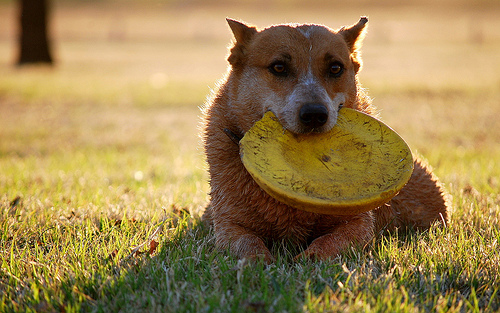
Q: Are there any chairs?
A: No, there are no chairs.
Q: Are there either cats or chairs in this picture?
A: No, there are no chairs or cats.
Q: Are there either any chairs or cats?
A: No, there are no chairs or cats.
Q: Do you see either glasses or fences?
A: No, there are no fences or glasses.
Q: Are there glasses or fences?
A: No, there are no fences or glasses.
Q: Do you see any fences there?
A: No, there are no fences.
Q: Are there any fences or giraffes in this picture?
A: No, there are no fences or giraffes.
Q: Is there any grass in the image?
A: Yes, there is grass.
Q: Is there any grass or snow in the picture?
A: Yes, there is grass.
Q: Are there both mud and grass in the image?
A: No, there is grass but no mud.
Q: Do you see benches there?
A: No, there are no benches.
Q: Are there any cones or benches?
A: No, there are no benches or cones.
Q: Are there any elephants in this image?
A: No, there are no elephants.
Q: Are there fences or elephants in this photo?
A: No, there are no elephants or fences.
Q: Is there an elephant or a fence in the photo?
A: No, there are no elephants or fences.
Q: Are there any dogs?
A: Yes, there is a dog.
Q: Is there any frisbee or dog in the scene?
A: Yes, there is a dog.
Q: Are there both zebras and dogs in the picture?
A: No, there is a dog but no zebras.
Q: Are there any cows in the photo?
A: No, there are no cows.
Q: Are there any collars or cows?
A: No, there are no cows or collars.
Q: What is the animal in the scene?
A: The animal is a dog.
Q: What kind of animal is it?
A: The animal is a dog.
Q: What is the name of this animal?
A: That is a dog.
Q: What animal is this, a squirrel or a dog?
A: That is a dog.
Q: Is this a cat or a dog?
A: This is a dog.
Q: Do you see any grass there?
A: Yes, there is grass.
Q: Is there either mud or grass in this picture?
A: Yes, there is grass.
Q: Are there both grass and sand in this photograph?
A: No, there is grass but no sand.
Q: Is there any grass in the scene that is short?
A: Yes, there is short grass.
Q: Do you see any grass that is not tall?
A: Yes, there is short grass.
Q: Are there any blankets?
A: No, there are no blankets.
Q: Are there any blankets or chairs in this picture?
A: No, there are no blankets or chairs.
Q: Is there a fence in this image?
A: No, there are no fences.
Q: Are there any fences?
A: No, there are no fences.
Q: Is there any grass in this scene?
A: Yes, there is grass.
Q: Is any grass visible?
A: Yes, there is grass.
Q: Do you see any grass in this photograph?
A: Yes, there is grass.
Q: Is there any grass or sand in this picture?
A: Yes, there is grass.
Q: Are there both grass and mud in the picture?
A: No, there is grass but no mud.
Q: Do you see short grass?
A: Yes, there is short grass.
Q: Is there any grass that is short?
A: Yes, there is grass that is short.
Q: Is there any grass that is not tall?
A: Yes, there is short grass.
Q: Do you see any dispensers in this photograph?
A: No, there are no dispensers.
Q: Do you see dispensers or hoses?
A: No, there are no dispensers or hoses.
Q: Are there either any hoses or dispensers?
A: No, there are no dispensers or hoses.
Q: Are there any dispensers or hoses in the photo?
A: No, there are no dispensers or hoses.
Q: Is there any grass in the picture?
A: Yes, there is grass.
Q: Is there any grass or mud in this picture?
A: Yes, there is grass.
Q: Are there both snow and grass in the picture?
A: No, there is grass but no snow.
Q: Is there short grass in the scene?
A: Yes, there is short grass.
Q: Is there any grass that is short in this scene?
A: Yes, there is short grass.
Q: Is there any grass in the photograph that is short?
A: Yes, there is grass that is short.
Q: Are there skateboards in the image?
A: No, there are no skateboards.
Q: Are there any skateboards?
A: No, there are no skateboards.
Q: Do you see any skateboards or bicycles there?
A: No, there are no skateboards or bicycles.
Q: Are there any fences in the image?
A: No, there are no fences.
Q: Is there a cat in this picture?
A: No, there are no cats.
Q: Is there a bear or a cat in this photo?
A: No, there are no cats or bears.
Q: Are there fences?
A: No, there are no fences.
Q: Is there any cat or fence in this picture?
A: No, there are no fences or cats.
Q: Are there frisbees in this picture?
A: Yes, there is a frisbee.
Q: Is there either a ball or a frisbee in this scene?
A: Yes, there is a frisbee.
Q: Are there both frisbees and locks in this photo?
A: No, there is a frisbee but no locks.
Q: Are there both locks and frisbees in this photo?
A: No, there is a frisbee but no locks.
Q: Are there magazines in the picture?
A: No, there are no magazines.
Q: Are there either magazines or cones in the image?
A: No, there are no magazines or cones.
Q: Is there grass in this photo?
A: Yes, there is grass.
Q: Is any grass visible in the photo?
A: Yes, there is grass.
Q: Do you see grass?
A: Yes, there is grass.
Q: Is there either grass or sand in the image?
A: Yes, there is grass.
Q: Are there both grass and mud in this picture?
A: No, there is grass but no mud.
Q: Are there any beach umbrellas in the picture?
A: No, there are no beach umbrellas.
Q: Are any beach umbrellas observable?
A: No, there are no beach umbrellas.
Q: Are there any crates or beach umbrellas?
A: No, there are no beach umbrellas or crates.